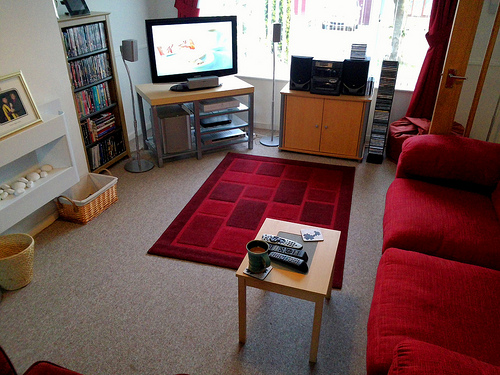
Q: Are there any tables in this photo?
A: Yes, there is a table.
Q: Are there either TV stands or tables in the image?
A: Yes, there is a table.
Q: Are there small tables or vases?
A: Yes, there is a small table.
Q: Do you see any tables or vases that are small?
A: Yes, the table is small.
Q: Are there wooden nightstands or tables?
A: Yes, there is a wood table.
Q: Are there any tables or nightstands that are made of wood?
A: Yes, the table is made of wood.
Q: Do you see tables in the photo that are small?
A: Yes, there is a small table.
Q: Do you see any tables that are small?
A: Yes, there is a table that is small.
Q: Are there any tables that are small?
A: Yes, there is a table that is small.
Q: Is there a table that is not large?
A: Yes, there is a small table.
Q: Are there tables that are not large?
A: Yes, there is a small table.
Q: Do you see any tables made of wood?
A: Yes, there is a table that is made of wood.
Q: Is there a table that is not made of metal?
A: Yes, there is a table that is made of wood.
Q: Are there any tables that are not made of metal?
A: Yes, there is a table that is made of wood.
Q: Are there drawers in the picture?
A: No, there are no drawers.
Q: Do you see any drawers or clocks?
A: No, there are no drawers or clocks.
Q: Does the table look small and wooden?
A: Yes, the table is small and wooden.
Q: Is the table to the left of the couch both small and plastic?
A: No, the table is small but wooden.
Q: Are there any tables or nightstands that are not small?
A: No, there is a table but it is small.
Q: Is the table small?
A: Yes, the table is small.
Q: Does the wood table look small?
A: Yes, the table is small.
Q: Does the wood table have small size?
A: Yes, the table is small.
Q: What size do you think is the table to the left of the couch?
A: The table is small.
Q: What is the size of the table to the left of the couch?
A: The table is small.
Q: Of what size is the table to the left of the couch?
A: The table is small.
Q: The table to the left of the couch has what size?
A: The table is small.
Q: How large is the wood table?
A: The table is small.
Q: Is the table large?
A: No, the table is small.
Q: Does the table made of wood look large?
A: No, the table is small.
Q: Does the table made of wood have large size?
A: No, the table is small.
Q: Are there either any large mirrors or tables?
A: No, there is a table but it is small.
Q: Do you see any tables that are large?
A: No, there is a table but it is small.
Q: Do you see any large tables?
A: No, there is a table but it is small.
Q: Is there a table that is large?
A: No, there is a table but it is small.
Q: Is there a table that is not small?
A: No, there is a table but it is small.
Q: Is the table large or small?
A: The table is small.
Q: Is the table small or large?
A: The table is small.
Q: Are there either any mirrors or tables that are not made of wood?
A: No, there is a table but it is made of wood.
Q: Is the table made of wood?
A: Yes, the table is made of wood.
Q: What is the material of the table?
A: The table is made of wood.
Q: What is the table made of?
A: The table is made of wood.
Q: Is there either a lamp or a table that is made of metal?
A: No, there is a table but it is made of wood.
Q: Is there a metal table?
A: No, there is a table but it is made of wood.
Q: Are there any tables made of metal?
A: No, there is a table but it is made of wood.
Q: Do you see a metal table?
A: No, there is a table but it is made of wood.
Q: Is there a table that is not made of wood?
A: No, there is a table but it is made of wood.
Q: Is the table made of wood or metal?
A: The table is made of wood.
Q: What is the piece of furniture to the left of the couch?
A: The piece of furniture is a table.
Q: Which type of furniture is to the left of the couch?
A: The piece of furniture is a table.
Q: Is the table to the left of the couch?
A: Yes, the table is to the left of the couch.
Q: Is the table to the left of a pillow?
A: No, the table is to the left of the couch.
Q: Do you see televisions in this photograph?
A: Yes, there is a television.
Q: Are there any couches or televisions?
A: Yes, there is a television.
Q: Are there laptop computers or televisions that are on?
A: Yes, the television is on.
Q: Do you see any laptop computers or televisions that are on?
A: Yes, the television is on.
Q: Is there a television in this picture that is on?
A: Yes, there is a television that is on.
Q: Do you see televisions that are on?
A: Yes, there is a television that is on.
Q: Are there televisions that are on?
A: Yes, there is a television that is on.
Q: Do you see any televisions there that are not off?
A: Yes, there is a television that is on .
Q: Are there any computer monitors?
A: No, there are no computer monitors.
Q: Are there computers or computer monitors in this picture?
A: No, there are no computer monitors or computers.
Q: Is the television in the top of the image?
A: Yes, the television is in the top of the image.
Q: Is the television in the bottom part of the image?
A: No, the television is in the top of the image.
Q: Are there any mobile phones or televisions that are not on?
A: No, there is a television but it is on.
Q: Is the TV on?
A: Yes, the TV is on.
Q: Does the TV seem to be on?
A: Yes, the TV is on.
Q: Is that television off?
A: No, the television is on.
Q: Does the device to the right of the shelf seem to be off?
A: No, the TV is on.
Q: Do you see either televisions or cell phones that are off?
A: No, there is a television but it is on.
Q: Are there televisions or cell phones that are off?
A: No, there is a television but it is on.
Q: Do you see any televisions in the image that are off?
A: No, there is a television but it is on.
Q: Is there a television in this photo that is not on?
A: No, there is a television but it is on.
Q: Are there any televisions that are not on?
A: No, there is a television but it is on.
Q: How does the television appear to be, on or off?
A: The television is on.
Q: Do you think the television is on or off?
A: The television is on.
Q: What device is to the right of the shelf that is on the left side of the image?
A: The device is a television.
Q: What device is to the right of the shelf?
A: The device is a television.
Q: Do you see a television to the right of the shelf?
A: Yes, there is a television to the right of the shelf.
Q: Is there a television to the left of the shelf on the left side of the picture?
A: No, the television is to the right of the shelf.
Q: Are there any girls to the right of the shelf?
A: No, there is a television to the right of the shelf.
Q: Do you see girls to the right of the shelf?
A: No, there is a television to the right of the shelf.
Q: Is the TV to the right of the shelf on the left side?
A: Yes, the TV is to the right of the shelf.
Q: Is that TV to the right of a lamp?
A: No, the TV is to the right of the shelf.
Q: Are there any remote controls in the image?
A: Yes, there is a remote control.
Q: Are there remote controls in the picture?
A: Yes, there is a remote control.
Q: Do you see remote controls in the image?
A: Yes, there is a remote control.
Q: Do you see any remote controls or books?
A: Yes, there is a remote control.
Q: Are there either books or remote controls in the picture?
A: Yes, there is a remote control.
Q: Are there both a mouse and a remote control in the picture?
A: No, there is a remote control but no computer mice.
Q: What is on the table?
A: The remote is on the table.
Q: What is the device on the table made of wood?
A: The device is a remote control.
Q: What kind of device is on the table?
A: The device is a remote control.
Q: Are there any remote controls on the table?
A: Yes, there is a remote control on the table.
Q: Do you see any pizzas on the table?
A: No, there is a remote control on the table.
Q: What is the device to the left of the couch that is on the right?
A: The device is a remote control.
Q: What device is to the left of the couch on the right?
A: The device is a remote control.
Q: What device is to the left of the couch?
A: The device is a remote control.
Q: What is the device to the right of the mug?
A: The device is a remote control.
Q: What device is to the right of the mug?
A: The device is a remote control.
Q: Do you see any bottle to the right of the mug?
A: No, there is a remote control to the right of the mug.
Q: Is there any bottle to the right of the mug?
A: No, there is a remote control to the right of the mug.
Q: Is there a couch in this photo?
A: Yes, there is a couch.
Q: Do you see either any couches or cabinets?
A: Yes, there is a couch.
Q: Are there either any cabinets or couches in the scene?
A: Yes, there is a couch.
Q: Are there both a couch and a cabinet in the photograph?
A: Yes, there are both a couch and a cabinet.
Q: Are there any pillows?
A: No, there are no pillows.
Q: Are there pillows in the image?
A: No, there are no pillows.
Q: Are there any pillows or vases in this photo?
A: No, there are no pillows or vases.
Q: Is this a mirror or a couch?
A: This is a couch.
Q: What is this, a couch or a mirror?
A: This is a couch.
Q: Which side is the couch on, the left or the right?
A: The couch is on the right of the image.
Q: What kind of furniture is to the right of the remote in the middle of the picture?
A: The piece of furniture is a couch.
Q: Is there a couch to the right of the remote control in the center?
A: Yes, there is a couch to the right of the remote control.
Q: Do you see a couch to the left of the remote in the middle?
A: No, the couch is to the right of the remote.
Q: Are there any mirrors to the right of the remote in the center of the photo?
A: No, there is a couch to the right of the remote control.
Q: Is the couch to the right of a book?
A: No, the couch is to the right of the remote.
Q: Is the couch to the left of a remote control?
A: No, the couch is to the right of a remote control.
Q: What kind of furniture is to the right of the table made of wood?
A: The piece of furniture is a couch.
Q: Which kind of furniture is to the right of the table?
A: The piece of furniture is a couch.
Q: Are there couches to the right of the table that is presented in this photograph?
A: Yes, there is a couch to the right of the table.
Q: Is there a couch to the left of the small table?
A: No, the couch is to the right of the table.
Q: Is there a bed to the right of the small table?
A: No, there is a couch to the right of the table.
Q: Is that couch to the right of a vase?
A: No, the couch is to the right of a table.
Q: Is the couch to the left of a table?
A: No, the couch is to the right of a table.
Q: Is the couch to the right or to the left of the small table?
A: The couch is to the right of the table.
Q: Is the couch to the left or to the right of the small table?
A: The couch is to the right of the table.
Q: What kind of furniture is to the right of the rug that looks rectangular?
A: The piece of furniture is a couch.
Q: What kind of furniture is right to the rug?
A: The piece of furniture is a couch.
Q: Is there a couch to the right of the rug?
A: Yes, there is a couch to the right of the rug.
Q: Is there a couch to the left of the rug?
A: No, the couch is to the right of the rug.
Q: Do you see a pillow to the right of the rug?
A: No, there is a couch to the right of the rug.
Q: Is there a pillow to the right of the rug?
A: No, there is a couch to the right of the rug.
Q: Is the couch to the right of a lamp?
A: No, the couch is to the right of a rug.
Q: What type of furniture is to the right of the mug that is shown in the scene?
A: The piece of furniture is a couch.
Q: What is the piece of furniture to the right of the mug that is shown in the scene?
A: The piece of furniture is a couch.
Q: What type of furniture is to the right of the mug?
A: The piece of furniture is a couch.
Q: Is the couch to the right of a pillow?
A: No, the couch is to the right of the mug.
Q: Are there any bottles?
A: No, there are no bottles.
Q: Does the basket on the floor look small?
A: Yes, the basket is small.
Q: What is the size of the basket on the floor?
A: The basket is small.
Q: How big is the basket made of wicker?
A: The basket is small.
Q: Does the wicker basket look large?
A: No, the basket is small.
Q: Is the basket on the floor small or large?
A: The basket is small.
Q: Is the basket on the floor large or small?
A: The basket is small.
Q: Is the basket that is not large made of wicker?
A: Yes, the basket is made of wicker.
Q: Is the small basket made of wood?
A: No, the basket is made of wicker.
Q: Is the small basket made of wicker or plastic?
A: The basket is made of wicker.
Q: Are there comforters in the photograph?
A: No, there are no comforters.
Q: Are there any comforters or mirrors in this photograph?
A: No, there are no comforters or mirrors.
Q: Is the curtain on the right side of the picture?
A: Yes, the curtain is on the right of the image.